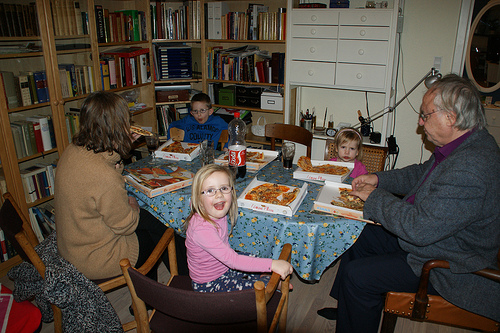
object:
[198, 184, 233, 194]
corrective lenses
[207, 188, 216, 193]
eyes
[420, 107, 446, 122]
glasses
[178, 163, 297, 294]
girl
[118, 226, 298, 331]
chair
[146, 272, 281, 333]
cusions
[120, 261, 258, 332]
backrest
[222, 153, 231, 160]
pizza.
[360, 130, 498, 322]
coat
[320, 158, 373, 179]
shirt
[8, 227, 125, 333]
sweater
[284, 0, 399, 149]
shelves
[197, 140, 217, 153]
glass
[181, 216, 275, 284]
shirt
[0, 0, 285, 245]
bookshelf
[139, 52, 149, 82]
book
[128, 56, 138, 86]
book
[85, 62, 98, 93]
book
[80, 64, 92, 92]
book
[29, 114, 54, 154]
book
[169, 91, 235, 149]
boy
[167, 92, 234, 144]
young boy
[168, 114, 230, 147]
blue hoodie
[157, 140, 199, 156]
pizza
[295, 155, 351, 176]
pizza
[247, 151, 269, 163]
pizza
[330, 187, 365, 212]
pizza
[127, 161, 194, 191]
pizza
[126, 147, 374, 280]
table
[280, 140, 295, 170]
glass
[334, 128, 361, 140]
headband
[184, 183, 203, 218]
bhair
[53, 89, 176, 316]
woman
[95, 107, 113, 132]
hair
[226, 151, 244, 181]
soda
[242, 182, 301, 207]
pizza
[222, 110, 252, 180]
bottle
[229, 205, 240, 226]
hair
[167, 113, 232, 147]
shirt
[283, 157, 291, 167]
liquid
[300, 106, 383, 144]
items